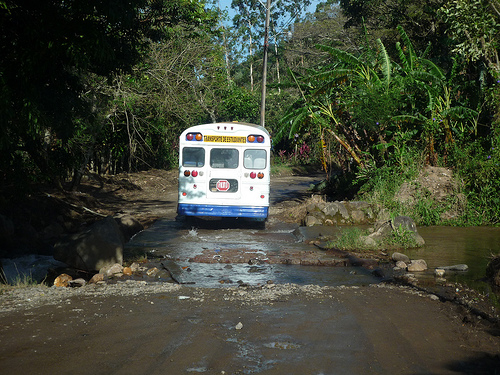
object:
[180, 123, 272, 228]
bus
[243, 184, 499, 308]
water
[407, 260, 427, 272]
stones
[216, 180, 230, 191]
sign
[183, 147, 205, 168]
windows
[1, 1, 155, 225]
trees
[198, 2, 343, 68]
sky